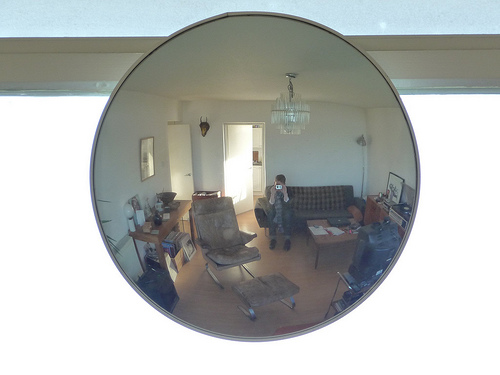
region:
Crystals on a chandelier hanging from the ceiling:
[272, 99, 309, 135]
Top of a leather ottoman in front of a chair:
[236, 271, 302, 308]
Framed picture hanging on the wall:
[136, 138, 158, 180]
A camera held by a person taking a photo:
[273, 180, 283, 191]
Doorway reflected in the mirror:
[219, 124, 265, 189]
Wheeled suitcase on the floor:
[362, 225, 399, 252]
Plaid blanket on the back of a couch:
[323, 188, 342, 203]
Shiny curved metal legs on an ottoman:
[247, 307, 257, 324]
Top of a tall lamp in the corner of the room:
[352, 131, 370, 151]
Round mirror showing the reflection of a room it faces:
[77, 11, 436, 340]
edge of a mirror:
[119, 266, 166, 296]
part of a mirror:
[363, 265, 388, 292]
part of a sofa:
[278, 187, 299, 209]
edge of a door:
[221, 155, 233, 187]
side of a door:
[219, 161, 227, 212]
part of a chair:
[186, 205, 257, 284]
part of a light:
[284, 111, 292, 118]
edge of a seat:
[218, 266, 227, 276]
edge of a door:
[223, 146, 230, 176]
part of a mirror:
[283, 103, 315, 174]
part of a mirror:
[271, 249, 313, 319]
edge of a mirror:
[299, 296, 349, 361]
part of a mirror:
[293, 267, 345, 350]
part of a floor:
[220, 300, 245, 330]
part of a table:
[251, 268, 275, 309]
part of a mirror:
[247, 243, 292, 304]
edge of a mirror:
[283, 313, 319, 355]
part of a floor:
[281, 305, 303, 334]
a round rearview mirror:
[85, 8, 425, 353]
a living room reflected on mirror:
[103, 56, 410, 321]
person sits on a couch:
[250, 169, 367, 249]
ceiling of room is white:
[166, 39, 357, 106]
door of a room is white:
[219, 118, 270, 210]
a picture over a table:
[130, 133, 160, 181]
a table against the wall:
[129, 188, 199, 273]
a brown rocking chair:
[186, 191, 271, 296]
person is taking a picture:
[260, 170, 300, 212]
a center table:
[302, 209, 367, 263]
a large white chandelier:
[270, 78, 318, 137]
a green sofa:
[251, 183, 360, 227]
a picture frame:
[135, 130, 157, 177]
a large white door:
[166, 120, 192, 205]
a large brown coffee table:
[306, 215, 361, 266]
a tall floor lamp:
[352, 135, 369, 195]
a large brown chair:
[191, 193, 267, 286]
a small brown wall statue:
[195, 113, 212, 136]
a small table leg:
[311, 241, 323, 266]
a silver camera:
[273, 180, 283, 191]